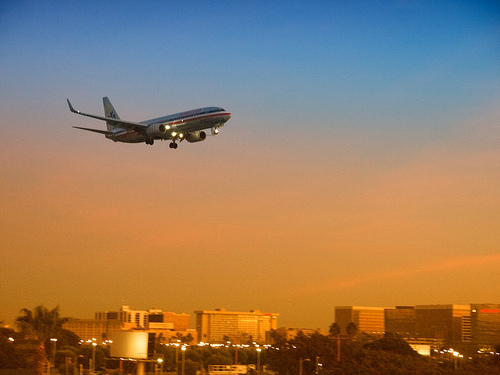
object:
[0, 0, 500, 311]
floor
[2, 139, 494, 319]
cloud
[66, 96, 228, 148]
airliner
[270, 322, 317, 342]
tall buildings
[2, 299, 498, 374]
city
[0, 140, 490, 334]
glow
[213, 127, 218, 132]
light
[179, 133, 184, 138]
light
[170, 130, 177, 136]
light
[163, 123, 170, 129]
light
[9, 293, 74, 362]
tree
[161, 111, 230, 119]
stripe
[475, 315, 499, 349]
building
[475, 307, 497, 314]
red lettering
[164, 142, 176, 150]
gear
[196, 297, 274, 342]
skyscaper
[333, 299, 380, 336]
skyscaper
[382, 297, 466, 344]
skyscaper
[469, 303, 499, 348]
skyscaper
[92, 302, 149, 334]
skyscaper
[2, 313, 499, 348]
horizon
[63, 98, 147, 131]
wings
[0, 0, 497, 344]
sky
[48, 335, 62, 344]
lights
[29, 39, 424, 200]
flight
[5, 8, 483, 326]
air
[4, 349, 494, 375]
street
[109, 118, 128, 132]
marks